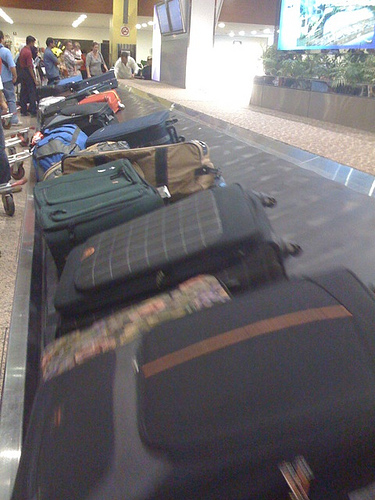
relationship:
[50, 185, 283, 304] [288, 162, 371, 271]
suitcase on a belt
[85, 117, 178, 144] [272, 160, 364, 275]
suitcase on a belt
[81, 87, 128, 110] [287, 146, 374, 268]
suitcase on a belt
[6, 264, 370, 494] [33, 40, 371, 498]
suitcase on a baggage claim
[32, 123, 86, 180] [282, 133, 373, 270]
bag on a belt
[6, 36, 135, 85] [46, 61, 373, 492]
people waiting for luggage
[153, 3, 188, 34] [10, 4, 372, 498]
moniter in an airport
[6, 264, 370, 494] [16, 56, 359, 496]
suitcase on an airport carousel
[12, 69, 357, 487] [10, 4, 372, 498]
carousel at an airport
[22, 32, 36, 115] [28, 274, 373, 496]
man waiting for luggage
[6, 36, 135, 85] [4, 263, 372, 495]
people waiting for luggage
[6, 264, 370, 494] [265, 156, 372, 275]
suitcase on a conveyor belt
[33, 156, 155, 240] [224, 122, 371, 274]
suitcase on a conveyor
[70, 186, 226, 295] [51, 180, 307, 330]
pocket on suitcase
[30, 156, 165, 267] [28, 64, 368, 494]
luggage on conveyor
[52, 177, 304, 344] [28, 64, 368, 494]
luggage on conveyor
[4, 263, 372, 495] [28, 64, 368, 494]
luggage on conveyor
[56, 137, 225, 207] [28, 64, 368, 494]
luggage on conveyor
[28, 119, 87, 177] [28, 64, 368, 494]
luggage on conveyor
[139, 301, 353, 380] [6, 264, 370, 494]
stripe on suitcase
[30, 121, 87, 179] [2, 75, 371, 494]
bag on conveyor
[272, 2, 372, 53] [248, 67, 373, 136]
monitor hanging over conveyor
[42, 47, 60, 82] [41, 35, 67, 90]
shirt on man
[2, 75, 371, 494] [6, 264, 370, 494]
conveyor loaded with suitcase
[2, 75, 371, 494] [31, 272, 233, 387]
conveyor loaded with suitcase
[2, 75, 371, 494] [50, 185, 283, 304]
conveyor loaded with suitcase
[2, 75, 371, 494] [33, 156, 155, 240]
conveyor loaded with suitcase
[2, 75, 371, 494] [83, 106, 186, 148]
conveyor loaded with suitcase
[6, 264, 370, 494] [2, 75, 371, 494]
suitcase on conveyor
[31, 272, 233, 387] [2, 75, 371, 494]
suitcase on conveyor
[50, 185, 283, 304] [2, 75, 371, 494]
suitcase on conveyor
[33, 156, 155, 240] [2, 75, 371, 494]
suitcase on conveyor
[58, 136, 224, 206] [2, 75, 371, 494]
suitcase on conveyor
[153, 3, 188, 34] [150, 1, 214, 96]
moniter on wall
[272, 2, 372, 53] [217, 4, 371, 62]
monitor on wall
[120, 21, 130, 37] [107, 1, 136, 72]
sign on wall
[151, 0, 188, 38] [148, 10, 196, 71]
screen on wall